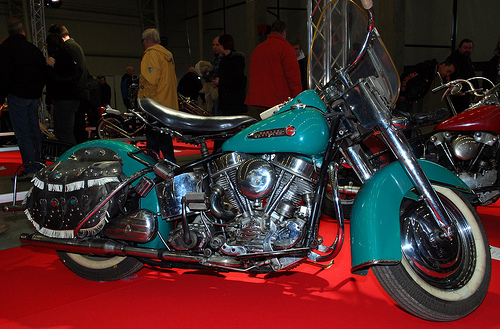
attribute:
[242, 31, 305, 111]
jacket — orange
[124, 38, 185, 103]
jacket — yellow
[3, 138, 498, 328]
carpet — red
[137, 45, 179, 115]
jacket —  yellow, yellow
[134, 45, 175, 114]
jacket —  yellow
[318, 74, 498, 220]
motorcycle —  large ,  red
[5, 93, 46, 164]
jeans —  blue,  man's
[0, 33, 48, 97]
top —  man's,   black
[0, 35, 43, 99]
top —   black,  man's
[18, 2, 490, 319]
motorcycles —  two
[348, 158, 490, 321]
wheel —  the front,  motorcycle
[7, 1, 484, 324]
motorcycle — red,  large,  turquoise, displayed, green, old, blue, black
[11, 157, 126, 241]
saddle bag — black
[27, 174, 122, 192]
fringe — white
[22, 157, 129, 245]
saddle bag — black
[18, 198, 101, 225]
studs — decorative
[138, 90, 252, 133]
motorcycle seat — black, molded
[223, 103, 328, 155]
gas tank — red, painted, aqua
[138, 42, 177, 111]
jacket — large, yellow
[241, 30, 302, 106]
jacket — red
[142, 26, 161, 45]
hair — short, cut, gray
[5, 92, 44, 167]
jean pants — blue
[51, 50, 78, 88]
purse — black